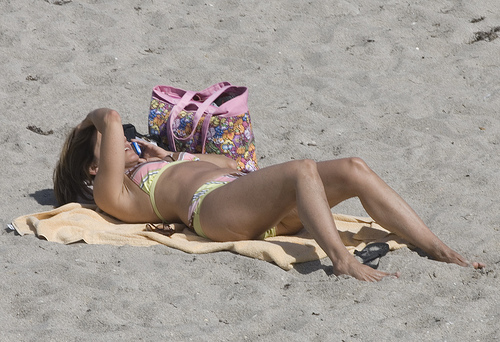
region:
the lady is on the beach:
[51, 105, 484, 281]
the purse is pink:
[149, 82, 260, 169]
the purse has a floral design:
[148, 83, 259, 173]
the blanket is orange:
[12, 201, 416, 268]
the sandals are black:
[355, 244, 389, 271]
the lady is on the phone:
[132, 142, 144, 154]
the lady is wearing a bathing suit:
[51, 107, 488, 282]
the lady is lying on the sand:
[1, 0, 497, 339]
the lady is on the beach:
[0, 0, 497, 340]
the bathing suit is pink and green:
[125, 150, 277, 241]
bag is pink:
[136, 72, 278, 172]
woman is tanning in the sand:
[70, 94, 492, 311]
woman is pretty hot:
[48, 117, 469, 309]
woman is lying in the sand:
[43, 109, 465, 335]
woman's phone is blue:
[122, 113, 168, 190]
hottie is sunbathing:
[46, 122, 471, 300]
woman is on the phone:
[51, 112, 476, 294]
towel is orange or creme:
[22, 210, 368, 307]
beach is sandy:
[23, 87, 498, 297]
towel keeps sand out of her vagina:
[23, 205, 372, 300]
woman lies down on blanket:
[42, 78, 469, 305]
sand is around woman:
[3, 3, 498, 335]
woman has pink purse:
[124, 39, 280, 194]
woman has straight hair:
[32, 71, 167, 226]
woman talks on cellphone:
[107, 93, 176, 185]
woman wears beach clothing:
[90, 127, 277, 268]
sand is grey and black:
[0, 13, 493, 331]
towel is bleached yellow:
[6, 166, 416, 282]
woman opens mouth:
[96, 113, 151, 163]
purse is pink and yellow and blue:
[132, 64, 294, 186]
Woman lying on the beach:
[26, 98, 496, 298]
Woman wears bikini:
[45, 95, 490, 300]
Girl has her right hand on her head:
[46, 95, 491, 290]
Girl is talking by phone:
[45, 90, 490, 290]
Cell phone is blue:
[125, 132, 141, 157]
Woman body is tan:
[37, 100, 489, 310]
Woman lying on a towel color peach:
[20, 95, 495, 322]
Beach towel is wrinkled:
[7, 230, 299, 274]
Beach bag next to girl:
[139, 69, 265, 166]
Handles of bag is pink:
[136, 62, 267, 173]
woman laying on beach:
[38, 79, 445, 289]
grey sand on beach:
[289, 50, 407, 120]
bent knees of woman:
[269, 142, 389, 221]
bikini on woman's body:
[126, 152, 242, 216]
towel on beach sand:
[3, 197, 380, 273]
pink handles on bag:
[165, 72, 261, 137]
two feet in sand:
[326, 236, 467, 286]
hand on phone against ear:
[122, 130, 147, 166]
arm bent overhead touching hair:
[82, 100, 127, 185]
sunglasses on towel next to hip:
[137, 216, 188, 238]